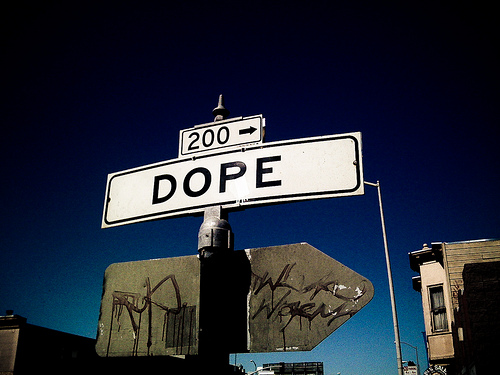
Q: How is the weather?
A: It is clear.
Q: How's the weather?
A: It is clear.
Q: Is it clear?
A: Yes, it is clear.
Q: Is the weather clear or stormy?
A: It is clear.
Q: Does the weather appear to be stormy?
A: No, it is clear.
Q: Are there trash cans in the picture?
A: No, there are no trash cans.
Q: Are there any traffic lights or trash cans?
A: No, there are no trash cans or traffic lights.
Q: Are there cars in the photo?
A: No, there are no cars.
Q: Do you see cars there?
A: No, there are no cars.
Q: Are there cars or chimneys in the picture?
A: No, there are no cars or chimneys.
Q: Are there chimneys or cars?
A: No, there are no cars or chimneys.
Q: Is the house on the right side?
A: Yes, the house is on the right of the image.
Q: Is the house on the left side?
A: No, the house is on the right of the image.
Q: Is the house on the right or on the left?
A: The house is on the right of the image.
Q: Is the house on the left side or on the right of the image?
A: The house is on the right of the image.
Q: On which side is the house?
A: The house is on the right of the image.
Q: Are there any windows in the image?
A: Yes, there is a window.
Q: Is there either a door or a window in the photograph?
A: Yes, there is a window.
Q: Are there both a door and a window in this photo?
A: No, there is a window but no doors.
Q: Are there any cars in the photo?
A: No, there are no cars.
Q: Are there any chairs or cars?
A: No, there are no cars or chairs.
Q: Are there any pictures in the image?
A: No, there are no pictures.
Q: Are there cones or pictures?
A: No, there are no pictures or cones.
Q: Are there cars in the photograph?
A: No, there are no cars.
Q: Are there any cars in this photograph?
A: No, there are no cars.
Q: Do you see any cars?
A: No, there are no cars.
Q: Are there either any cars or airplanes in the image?
A: No, there are no cars or airplanes.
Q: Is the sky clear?
A: Yes, the sky is clear.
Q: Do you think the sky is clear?
A: Yes, the sky is clear.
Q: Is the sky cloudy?
A: No, the sky is clear.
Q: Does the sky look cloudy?
A: No, the sky is clear.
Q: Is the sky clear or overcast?
A: The sky is clear.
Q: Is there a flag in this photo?
A: No, there are no flags.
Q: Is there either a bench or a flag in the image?
A: No, there are no flags or benches.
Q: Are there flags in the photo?
A: No, there are no flags.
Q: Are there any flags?
A: No, there are no flags.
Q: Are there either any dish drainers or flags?
A: No, there are no flags or dish drainers.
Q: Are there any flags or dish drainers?
A: No, there are no flags or dish drainers.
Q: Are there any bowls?
A: No, there are no bowls.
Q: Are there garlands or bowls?
A: No, there are no bowls or garlands.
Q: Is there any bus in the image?
A: No, there are no buses.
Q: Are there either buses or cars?
A: No, there are no buses or cars.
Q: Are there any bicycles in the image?
A: No, there are no bicycles.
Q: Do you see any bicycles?
A: No, there are no bicycles.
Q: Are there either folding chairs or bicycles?
A: No, there are no bicycles or folding chairs.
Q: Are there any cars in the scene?
A: No, there are no cars.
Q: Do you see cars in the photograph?
A: No, there are no cars.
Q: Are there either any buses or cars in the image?
A: No, there are no cars or buses.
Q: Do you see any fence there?
A: Yes, there is a fence.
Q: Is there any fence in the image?
A: Yes, there is a fence.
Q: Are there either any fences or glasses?
A: Yes, there is a fence.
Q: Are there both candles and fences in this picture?
A: No, there is a fence but no candles.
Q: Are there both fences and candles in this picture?
A: No, there is a fence but no candles.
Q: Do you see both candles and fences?
A: No, there is a fence but no candles.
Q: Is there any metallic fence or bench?
A: Yes, there is a metal fence.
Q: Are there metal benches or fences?
A: Yes, there is a metal fence.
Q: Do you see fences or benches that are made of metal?
A: Yes, the fence is made of metal.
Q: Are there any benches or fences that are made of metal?
A: Yes, the fence is made of metal.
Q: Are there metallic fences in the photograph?
A: Yes, there is a metal fence.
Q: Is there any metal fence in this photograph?
A: Yes, there is a metal fence.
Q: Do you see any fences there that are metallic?
A: Yes, there is a fence that is metallic.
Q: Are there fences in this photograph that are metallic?
A: Yes, there is a fence that is metallic.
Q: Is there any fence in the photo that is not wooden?
A: Yes, there is a metallic fence.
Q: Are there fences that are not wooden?
A: Yes, there is a metallic fence.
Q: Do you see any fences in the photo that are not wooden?
A: Yes, there is a metallic fence.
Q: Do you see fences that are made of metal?
A: Yes, there is a fence that is made of metal.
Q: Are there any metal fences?
A: Yes, there is a fence that is made of metal.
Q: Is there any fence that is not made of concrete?
A: Yes, there is a fence that is made of metal.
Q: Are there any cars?
A: No, there are no cars.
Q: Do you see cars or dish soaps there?
A: No, there are no cars or dish soaps.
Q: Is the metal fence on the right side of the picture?
A: Yes, the fence is on the right of the image.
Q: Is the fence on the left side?
A: No, the fence is on the right of the image.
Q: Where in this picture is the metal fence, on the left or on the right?
A: The fence is on the right of the image.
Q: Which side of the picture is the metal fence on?
A: The fence is on the right of the image.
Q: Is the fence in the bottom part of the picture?
A: Yes, the fence is in the bottom of the image.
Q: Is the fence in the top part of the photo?
A: No, the fence is in the bottom of the image.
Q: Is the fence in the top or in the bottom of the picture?
A: The fence is in the bottom of the image.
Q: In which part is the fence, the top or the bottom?
A: The fence is in the bottom of the image.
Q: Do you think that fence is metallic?
A: Yes, the fence is metallic.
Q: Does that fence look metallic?
A: Yes, the fence is metallic.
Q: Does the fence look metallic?
A: Yes, the fence is metallic.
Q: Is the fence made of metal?
A: Yes, the fence is made of metal.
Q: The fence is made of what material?
A: The fence is made of metal.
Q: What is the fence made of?
A: The fence is made of metal.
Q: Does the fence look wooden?
A: No, the fence is metallic.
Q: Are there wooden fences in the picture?
A: No, there is a fence but it is metallic.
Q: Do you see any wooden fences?
A: No, there is a fence but it is metallic.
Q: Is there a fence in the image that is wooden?
A: No, there is a fence but it is metallic.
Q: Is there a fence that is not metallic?
A: No, there is a fence but it is metallic.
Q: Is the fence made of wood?
A: No, the fence is made of metal.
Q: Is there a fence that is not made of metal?
A: No, there is a fence but it is made of metal.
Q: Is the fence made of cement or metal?
A: The fence is made of metal.